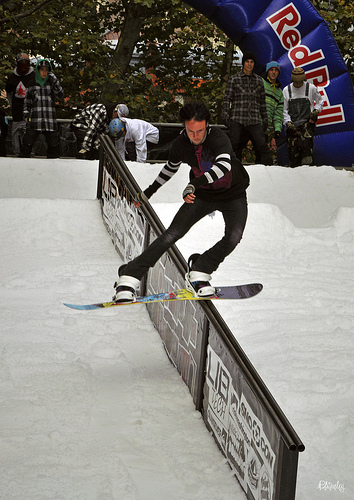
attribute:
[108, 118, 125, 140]
helmet — blue 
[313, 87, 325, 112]
sleeve — white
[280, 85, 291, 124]
sleeve — white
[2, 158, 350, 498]
snow — plenty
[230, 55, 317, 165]
men — two and young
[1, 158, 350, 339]
snow — white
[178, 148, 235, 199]
sleeve — black, white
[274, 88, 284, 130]
sleeves — green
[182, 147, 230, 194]
sleeve — striped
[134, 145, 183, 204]
sleeve — striped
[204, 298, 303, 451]
rail — metal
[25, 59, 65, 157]
man — young, black, white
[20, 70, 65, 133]
jacket — plaid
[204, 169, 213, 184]
stripe — white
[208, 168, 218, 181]
stripe — black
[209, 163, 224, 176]
stripe — black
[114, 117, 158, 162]
clothes — white, shirt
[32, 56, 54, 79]
hood — green 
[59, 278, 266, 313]
snowboard — colorful